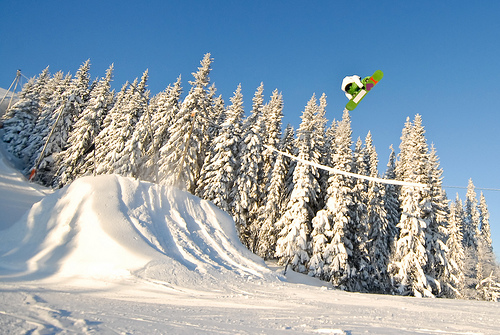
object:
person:
[340, 74, 367, 100]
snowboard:
[344, 68, 385, 112]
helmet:
[354, 73, 361, 78]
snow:
[151, 160, 204, 184]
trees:
[2, 51, 499, 300]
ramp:
[29, 167, 295, 295]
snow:
[9, 288, 499, 334]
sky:
[20, 1, 69, 59]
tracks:
[122, 176, 469, 334]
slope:
[1, 147, 493, 334]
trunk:
[281, 250, 297, 278]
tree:
[275, 129, 312, 278]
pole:
[1, 68, 24, 114]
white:
[340, 75, 365, 100]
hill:
[18, 167, 254, 334]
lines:
[10, 280, 119, 334]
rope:
[261, 141, 500, 201]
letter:
[369, 77, 380, 85]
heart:
[363, 81, 376, 92]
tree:
[173, 50, 218, 193]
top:
[189, 49, 221, 77]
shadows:
[1, 156, 87, 274]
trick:
[338, 67, 386, 115]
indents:
[275, 318, 429, 335]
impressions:
[111, 173, 274, 285]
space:
[351, 88, 367, 105]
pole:
[29, 102, 67, 182]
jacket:
[339, 74, 365, 100]